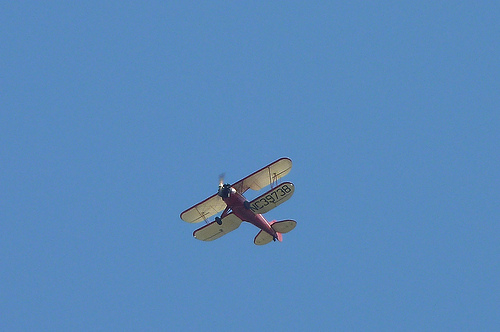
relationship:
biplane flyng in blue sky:
[181, 157, 297, 246] [2, 1, 482, 153]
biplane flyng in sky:
[181, 157, 297, 246] [0, 1, 456, 154]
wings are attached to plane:
[250, 156, 303, 206] [177, 151, 303, 250]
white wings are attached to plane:
[175, 189, 241, 242] [177, 151, 303, 250]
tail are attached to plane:
[255, 219, 299, 245] [177, 151, 303, 250]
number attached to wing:
[247, 175, 301, 210] [253, 180, 302, 212]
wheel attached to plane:
[208, 210, 228, 230] [177, 151, 303, 250]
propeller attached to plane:
[217, 172, 227, 193] [185, 150, 312, 266]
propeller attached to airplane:
[217, 172, 234, 192] [178, 150, 298, 254]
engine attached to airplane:
[215, 175, 235, 195] [178, 150, 298, 254]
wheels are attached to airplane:
[214, 189, 257, 226] [189, 158, 301, 248]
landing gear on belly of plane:
[210, 195, 253, 228] [177, 151, 303, 250]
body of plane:
[222, 182, 272, 226] [177, 151, 303, 250]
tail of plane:
[255, 219, 299, 245] [177, 151, 303, 250]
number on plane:
[247, 185, 293, 211] [177, 151, 303, 250]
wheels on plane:
[209, 197, 253, 227] [179, 148, 299, 257]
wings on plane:
[178, 145, 299, 245] [176, 153, 295, 256]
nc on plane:
[248, 199, 262, 211] [176, 153, 295, 256]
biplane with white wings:
[181, 157, 297, 246] [175, 189, 241, 242]